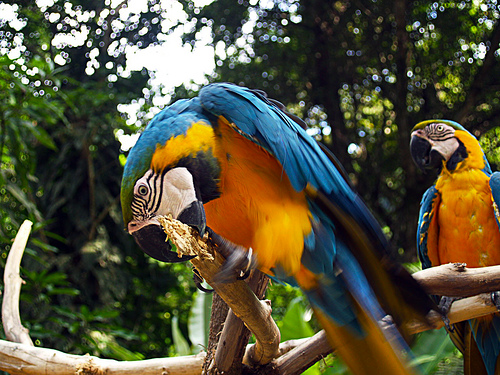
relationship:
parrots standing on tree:
[117, 89, 480, 262] [1, 3, 483, 357]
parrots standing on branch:
[117, 81, 438, 375] [4, 222, 481, 365]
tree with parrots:
[1, 216, 498, 373] [119, 80, 449, 372]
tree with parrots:
[1, 216, 498, 373] [407, 117, 498, 372]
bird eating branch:
[117, 83, 452, 373] [158, 215, 288, 355]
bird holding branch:
[117, 83, 452, 373] [150, 215, 280, 370]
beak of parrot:
[129, 197, 209, 262] [153, 82, 418, 336]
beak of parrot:
[129, 197, 209, 262] [116, 112, 286, 253]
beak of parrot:
[135, 205, 209, 266] [98, 83, 452, 373]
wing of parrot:
[195, 78, 440, 312] [55, 75, 452, 364]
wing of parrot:
[414, 187, 441, 269] [405, 117, 498, 374]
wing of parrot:
[195, 77, 373, 207] [98, 83, 452, 373]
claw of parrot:
[109, 73, 431, 368] [98, 83, 452, 373]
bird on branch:
[394, 114, 499, 285] [395, 254, 495, 289]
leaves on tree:
[341, 10, 459, 68] [0, 53, 96, 280]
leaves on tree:
[438, 78, 463, 96] [293, 10, 499, 120]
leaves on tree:
[327, 11, 461, 93] [5, 0, 228, 356]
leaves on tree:
[0, 1, 498, 361] [5, 0, 228, 356]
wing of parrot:
[195, 78, 440, 312] [132, 90, 410, 305]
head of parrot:
[409, 118, 486, 177] [405, 117, 498, 374]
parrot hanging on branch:
[400, 115, 499, 313] [3, 220, 287, 368]